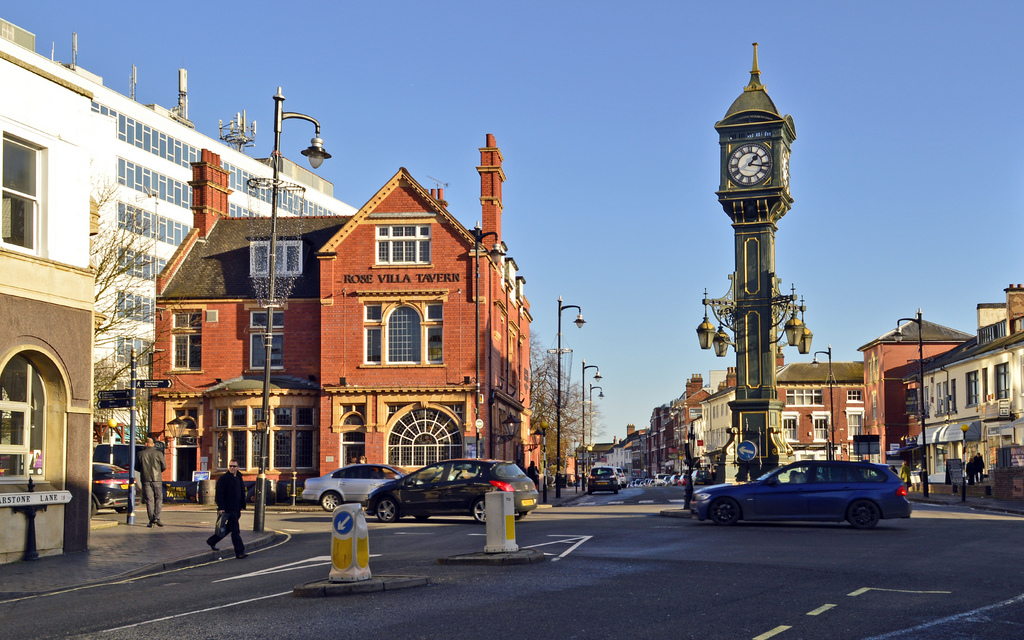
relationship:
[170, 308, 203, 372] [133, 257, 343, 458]
window on building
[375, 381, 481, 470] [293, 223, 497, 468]
windows on building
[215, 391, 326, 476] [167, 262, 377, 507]
windows on building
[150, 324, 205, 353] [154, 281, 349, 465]
window on building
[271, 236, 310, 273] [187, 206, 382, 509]
window on building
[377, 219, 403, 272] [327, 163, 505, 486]
window on building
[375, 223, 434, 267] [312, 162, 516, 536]
window on building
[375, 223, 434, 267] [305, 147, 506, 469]
window on building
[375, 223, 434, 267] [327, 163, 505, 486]
window on building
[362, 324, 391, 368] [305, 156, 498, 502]
window on building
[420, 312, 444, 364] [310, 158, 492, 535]
window on building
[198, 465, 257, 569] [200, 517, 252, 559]
man of legs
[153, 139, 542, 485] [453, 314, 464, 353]
building made brick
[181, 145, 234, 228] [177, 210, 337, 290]
chimney on roof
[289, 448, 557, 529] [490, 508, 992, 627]
cars on street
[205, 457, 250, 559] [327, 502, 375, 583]
man leaning curb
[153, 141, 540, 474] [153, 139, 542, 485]
window on building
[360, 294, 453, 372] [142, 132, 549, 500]
window on building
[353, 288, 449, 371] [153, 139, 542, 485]
window on building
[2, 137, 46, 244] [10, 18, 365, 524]
window on building